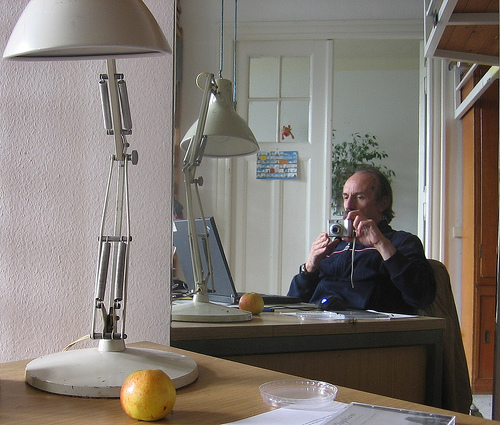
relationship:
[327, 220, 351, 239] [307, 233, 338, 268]
camera in hand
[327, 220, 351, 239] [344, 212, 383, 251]
camera in hand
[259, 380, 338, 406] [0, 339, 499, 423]
bowl on table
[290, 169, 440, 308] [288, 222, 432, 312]
man wearing pull over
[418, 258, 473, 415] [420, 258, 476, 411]
jacket on chair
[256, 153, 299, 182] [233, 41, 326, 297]
sign on door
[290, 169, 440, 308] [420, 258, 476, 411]
man sitting on chair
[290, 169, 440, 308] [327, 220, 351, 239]
man holding camera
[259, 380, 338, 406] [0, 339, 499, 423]
top on table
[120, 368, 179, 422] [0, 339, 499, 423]
apple on table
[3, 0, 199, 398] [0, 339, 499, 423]
lamp on table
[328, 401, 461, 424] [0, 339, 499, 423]
cd on table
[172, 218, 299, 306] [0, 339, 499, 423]
lap top on table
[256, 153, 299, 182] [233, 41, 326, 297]
picture on door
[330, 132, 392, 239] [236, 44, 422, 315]
plant in door way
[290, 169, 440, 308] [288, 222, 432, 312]
man wearing sweater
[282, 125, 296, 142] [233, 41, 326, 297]
decal on door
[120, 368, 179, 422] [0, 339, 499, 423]
apple on desk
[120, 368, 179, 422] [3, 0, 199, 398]
apple next to lamp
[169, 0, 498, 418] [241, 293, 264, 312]
mirror showing apple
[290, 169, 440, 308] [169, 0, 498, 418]
man in mirror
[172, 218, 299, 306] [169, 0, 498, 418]
lap top shown mirror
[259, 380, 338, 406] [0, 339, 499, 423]
lid on desk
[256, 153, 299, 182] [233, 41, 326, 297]
painting on door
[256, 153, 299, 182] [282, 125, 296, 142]
painting under decal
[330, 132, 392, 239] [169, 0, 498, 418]
plant seen in mirror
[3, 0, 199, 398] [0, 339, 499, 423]
lamp sitting on desk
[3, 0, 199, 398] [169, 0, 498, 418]
lamp seen through mirror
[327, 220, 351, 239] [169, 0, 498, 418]
camera in mirror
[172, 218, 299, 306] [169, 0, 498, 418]
lap top in mirror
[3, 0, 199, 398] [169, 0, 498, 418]
lamp in mirror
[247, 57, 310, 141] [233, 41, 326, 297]
panes in door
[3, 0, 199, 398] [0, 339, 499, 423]
lamp on desk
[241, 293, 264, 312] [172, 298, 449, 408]
apple on desk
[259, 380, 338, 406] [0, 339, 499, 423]
ashtray on desk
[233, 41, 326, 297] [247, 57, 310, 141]
door with panes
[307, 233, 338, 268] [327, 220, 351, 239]
hand holding camera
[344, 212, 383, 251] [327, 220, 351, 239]
hand holding camera